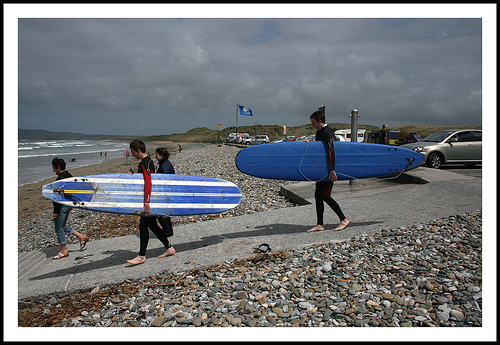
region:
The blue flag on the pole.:
[232, 95, 250, 137]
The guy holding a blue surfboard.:
[235, 109, 430, 239]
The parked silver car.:
[403, 119, 489, 181]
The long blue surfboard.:
[237, 138, 427, 188]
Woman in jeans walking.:
[42, 150, 89, 270]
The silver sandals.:
[48, 234, 99, 259]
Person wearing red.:
[121, 145, 130, 159]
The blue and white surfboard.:
[36, 173, 243, 217]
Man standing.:
[377, 121, 392, 140]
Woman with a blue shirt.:
[153, 143, 174, 174]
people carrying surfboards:
[41, 101, 423, 256]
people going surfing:
[39, 102, 426, 267]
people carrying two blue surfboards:
[42, 103, 424, 268]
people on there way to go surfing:
[43, 107, 423, 266]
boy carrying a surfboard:
[120, 133, 175, 267]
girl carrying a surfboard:
[237, 105, 422, 233]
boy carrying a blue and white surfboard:
[40, 138, 238, 262]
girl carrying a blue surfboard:
[235, 107, 418, 234]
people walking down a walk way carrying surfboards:
[40, 106, 418, 263]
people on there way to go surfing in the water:
[42, 104, 429, 265]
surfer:
[101, 119, 188, 273]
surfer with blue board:
[277, 75, 341, 232]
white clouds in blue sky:
[387, 13, 444, 58]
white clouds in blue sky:
[382, 59, 424, 106]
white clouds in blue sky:
[231, 36, 259, 60]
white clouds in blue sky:
[117, 43, 151, 84]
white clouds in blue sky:
[164, 22, 201, 59]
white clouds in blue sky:
[57, 33, 112, 85]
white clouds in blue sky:
[191, 55, 235, 110]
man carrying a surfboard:
[112, 138, 181, 260]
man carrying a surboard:
[260, 94, 375, 227]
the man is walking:
[45, 138, 79, 250]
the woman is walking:
[147, 127, 174, 231]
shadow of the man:
[82, 251, 126, 266]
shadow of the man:
[269, 213, 297, 242]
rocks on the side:
[349, 222, 457, 284]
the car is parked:
[442, 133, 476, 168]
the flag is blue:
[230, 98, 255, 145]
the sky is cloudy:
[75, 50, 138, 90]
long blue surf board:
[220, 139, 429, 188]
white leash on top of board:
[286, 142, 322, 177]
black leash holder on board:
[408, 154, 416, 160]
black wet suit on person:
[310, 122, 348, 222]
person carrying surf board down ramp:
[229, 93, 438, 260]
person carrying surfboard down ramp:
[42, 135, 239, 256]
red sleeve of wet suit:
[128, 165, 155, 217]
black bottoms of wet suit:
[134, 218, 175, 258]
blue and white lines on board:
[80, 180, 237, 211]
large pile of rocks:
[212, 235, 380, 326]